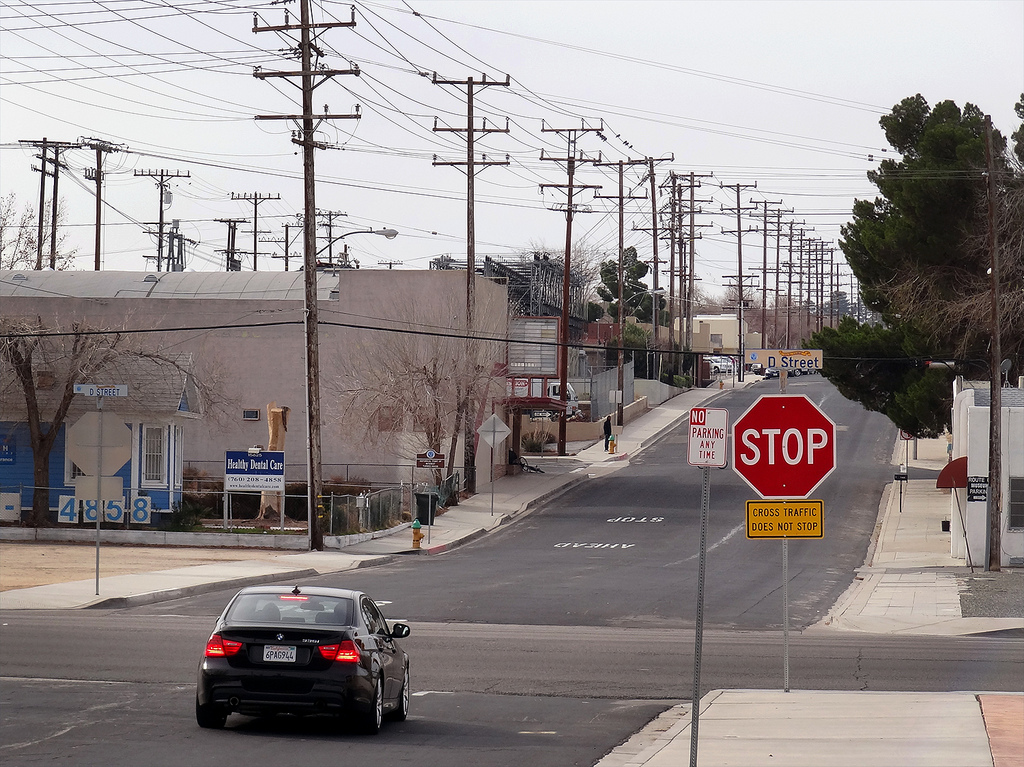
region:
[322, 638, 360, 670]
the light is red in color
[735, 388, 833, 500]
the sign is red in color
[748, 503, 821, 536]
the sign is yellow in color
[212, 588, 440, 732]
the car is black in color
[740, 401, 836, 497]
the sign says stop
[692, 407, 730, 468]
the sign says no parking any time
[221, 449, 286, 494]
the sign is blue and white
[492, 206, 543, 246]
the sky is blue in color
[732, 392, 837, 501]
the STOP sign is red and white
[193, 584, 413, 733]
the car is black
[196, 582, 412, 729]
the red lights on the car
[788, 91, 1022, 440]
the biggest tree has dark green leaves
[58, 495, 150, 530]
the blue numbers are large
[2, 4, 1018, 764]
the streets in the city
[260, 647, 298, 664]
license plate on car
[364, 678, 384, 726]
tire of a car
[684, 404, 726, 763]
side on the sidewalk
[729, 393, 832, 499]
red and white sign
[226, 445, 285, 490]
blue and white sign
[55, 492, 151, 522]
signs with some numbers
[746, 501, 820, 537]
yellow and black sign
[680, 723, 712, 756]
pole on the sidewalk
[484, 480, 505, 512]
pole on the sidewalk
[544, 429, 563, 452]
pole on the sidewalk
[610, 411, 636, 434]
pole on the sidewalk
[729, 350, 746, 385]
pole on the sidewalk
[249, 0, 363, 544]
utility pole in an industrialized city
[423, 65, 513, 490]
utility pole in an industrialized city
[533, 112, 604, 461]
utility pole in an industrialized city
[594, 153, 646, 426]
utility pole in an industrialized city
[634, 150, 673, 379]
utility pole in an industrialized city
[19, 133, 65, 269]
utility pole in an industrialized city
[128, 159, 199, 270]
utility pole in an industrialized city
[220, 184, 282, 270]
utility pole in an industrialized city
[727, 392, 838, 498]
stop sign on a pole on a corner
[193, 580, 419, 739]
black car sitting at a stop sign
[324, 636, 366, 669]
Taillight of a car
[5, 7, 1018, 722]
Powerlines hanging by power poles.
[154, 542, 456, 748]
A vehicle on the road.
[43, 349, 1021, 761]
The road.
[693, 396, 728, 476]
A red and white traffic sign.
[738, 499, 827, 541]
A yellow and black traffic sign.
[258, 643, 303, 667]
A license plate on a vehicle.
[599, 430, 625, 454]
A green and yellow fire hydrant.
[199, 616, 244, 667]
Taillight of a car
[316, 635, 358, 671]
Taillight of a black car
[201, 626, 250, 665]
Taillight of a black car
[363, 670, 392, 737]
Tire of a car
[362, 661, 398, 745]
Tire of a black car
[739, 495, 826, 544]
Black and orange sign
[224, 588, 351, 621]
Window of a car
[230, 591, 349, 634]
Window of a black car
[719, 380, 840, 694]
a red and white stop sign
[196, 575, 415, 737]
the back of a black car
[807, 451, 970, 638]
a long paved sidewalk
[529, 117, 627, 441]
a tall light pole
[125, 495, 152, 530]
a blue number eight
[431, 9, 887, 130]
long electrical power lines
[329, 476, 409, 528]
a gray chain link fence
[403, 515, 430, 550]
a yellow and blue fire hydrant